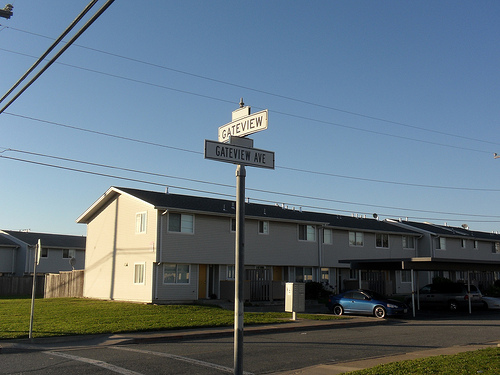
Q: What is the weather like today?
A: It is clear.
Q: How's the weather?
A: It is clear.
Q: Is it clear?
A: Yes, it is clear.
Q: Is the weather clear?
A: Yes, it is clear.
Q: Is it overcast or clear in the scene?
A: It is clear.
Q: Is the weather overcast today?
A: No, it is clear.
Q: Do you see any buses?
A: No, there are no buses.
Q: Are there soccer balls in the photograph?
A: No, there are no soccer balls.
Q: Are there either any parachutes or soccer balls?
A: No, there are no soccer balls or parachutes.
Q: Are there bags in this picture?
A: No, there are no bags.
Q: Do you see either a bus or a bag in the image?
A: No, there are no bags or buses.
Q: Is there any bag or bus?
A: No, there are no bags or buses.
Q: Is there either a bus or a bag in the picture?
A: No, there are no bags or buses.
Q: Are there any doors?
A: Yes, there is a door.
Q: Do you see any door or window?
A: Yes, there is a door.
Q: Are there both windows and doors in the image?
A: Yes, there are both a door and a window.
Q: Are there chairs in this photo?
A: No, there are no chairs.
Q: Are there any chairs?
A: No, there are no chairs.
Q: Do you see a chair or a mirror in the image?
A: No, there are no chairs or mirrors.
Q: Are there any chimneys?
A: No, there are no chimneys.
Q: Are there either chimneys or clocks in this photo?
A: No, there are no chimneys or clocks.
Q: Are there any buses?
A: No, there are no buses.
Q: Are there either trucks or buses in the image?
A: No, there are no buses or trucks.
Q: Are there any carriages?
A: No, there are no carriages.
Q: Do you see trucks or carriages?
A: No, there are no carriages or trucks.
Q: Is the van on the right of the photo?
A: Yes, the van is on the right of the image.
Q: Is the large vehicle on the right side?
A: Yes, the van is on the right of the image.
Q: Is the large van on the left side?
A: No, the van is on the right of the image.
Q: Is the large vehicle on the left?
A: No, the van is on the right of the image.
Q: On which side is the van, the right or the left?
A: The van is on the right of the image.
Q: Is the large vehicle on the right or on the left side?
A: The van is on the right of the image.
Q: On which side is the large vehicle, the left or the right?
A: The van is on the right of the image.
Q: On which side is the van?
A: The van is on the right of the image.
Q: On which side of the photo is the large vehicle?
A: The van is on the right of the image.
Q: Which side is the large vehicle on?
A: The van is on the right of the image.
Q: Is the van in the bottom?
A: Yes, the van is in the bottom of the image.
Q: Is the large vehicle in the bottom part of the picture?
A: Yes, the van is in the bottom of the image.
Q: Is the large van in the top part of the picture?
A: No, the van is in the bottom of the image.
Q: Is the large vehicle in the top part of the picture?
A: No, the van is in the bottom of the image.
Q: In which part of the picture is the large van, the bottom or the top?
A: The van is in the bottom of the image.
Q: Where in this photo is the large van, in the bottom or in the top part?
A: The van is in the bottom of the image.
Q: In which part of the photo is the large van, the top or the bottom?
A: The van is in the bottom of the image.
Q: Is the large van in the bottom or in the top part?
A: The van is in the bottom of the image.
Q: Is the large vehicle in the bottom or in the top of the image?
A: The van is in the bottom of the image.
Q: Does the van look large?
A: Yes, the van is large.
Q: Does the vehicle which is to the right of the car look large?
A: Yes, the van is large.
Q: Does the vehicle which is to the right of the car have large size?
A: Yes, the van is large.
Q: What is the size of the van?
A: The van is large.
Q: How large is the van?
A: The van is large.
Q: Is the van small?
A: No, the van is large.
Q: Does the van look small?
A: No, the van is large.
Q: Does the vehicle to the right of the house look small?
A: No, the van is large.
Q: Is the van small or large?
A: The van is large.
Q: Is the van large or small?
A: The van is large.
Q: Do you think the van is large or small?
A: The van is large.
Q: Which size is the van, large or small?
A: The van is large.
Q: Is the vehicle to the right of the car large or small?
A: The van is large.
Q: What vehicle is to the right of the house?
A: The vehicle is a van.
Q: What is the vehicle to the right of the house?
A: The vehicle is a van.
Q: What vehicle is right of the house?
A: The vehicle is a van.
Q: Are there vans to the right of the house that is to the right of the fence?
A: Yes, there is a van to the right of the house.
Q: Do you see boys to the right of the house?
A: No, there is a van to the right of the house.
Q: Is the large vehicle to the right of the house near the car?
A: Yes, the van is to the right of the house.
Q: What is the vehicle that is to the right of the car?
A: The vehicle is a van.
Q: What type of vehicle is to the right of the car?
A: The vehicle is a van.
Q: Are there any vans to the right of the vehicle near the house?
A: Yes, there is a van to the right of the car.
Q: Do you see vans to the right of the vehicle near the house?
A: Yes, there is a van to the right of the car.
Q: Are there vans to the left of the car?
A: No, the van is to the right of the car.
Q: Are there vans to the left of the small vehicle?
A: No, the van is to the right of the car.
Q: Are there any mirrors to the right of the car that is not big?
A: No, there is a van to the right of the car.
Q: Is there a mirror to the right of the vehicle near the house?
A: No, there is a van to the right of the car.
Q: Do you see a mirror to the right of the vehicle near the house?
A: No, there is a van to the right of the car.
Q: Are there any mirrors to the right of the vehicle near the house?
A: No, there is a van to the right of the car.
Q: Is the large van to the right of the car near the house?
A: Yes, the van is to the right of the car.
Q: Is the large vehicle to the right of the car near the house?
A: Yes, the van is to the right of the car.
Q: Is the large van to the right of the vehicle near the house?
A: Yes, the van is to the right of the car.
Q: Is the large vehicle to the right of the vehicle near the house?
A: Yes, the van is to the right of the car.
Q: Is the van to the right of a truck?
A: No, the van is to the right of the car.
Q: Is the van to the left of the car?
A: No, the van is to the right of the car.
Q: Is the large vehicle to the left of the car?
A: No, the van is to the right of the car.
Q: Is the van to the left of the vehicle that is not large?
A: No, the van is to the right of the car.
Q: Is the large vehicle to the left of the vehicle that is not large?
A: No, the van is to the right of the car.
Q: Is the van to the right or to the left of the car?
A: The van is to the right of the car.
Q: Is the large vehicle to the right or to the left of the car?
A: The van is to the right of the car.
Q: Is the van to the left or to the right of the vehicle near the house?
A: The van is to the right of the car.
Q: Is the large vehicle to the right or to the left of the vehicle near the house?
A: The van is to the right of the car.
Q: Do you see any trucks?
A: No, there are no trucks.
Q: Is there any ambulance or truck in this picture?
A: No, there are no trucks or ambulances.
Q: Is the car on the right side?
A: Yes, the car is on the right of the image.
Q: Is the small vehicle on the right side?
A: Yes, the car is on the right of the image.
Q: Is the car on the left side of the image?
A: No, the car is on the right of the image.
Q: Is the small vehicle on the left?
A: No, the car is on the right of the image.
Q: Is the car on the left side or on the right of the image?
A: The car is on the right of the image.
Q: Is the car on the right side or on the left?
A: The car is on the right of the image.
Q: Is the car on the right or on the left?
A: The car is on the right of the image.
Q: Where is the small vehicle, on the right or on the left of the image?
A: The car is on the right of the image.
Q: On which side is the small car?
A: The car is on the right of the image.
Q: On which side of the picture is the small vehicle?
A: The car is on the right of the image.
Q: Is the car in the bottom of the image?
A: Yes, the car is in the bottom of the image.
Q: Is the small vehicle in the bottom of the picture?
A: Yes, the car is in the bottom of the image.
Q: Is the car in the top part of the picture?
A: No, the car is in the bottom of the image.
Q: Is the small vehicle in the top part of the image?
A: No, the car is in the bottom of the image.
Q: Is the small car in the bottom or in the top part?
A: The car is in the bottom of the image.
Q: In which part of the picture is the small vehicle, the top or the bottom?
A: The car is in the bottom of the image.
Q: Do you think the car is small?
A: Yes, the car is small.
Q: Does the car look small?
A: Yes, the car is small.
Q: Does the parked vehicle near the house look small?
A: Yes, the car is small.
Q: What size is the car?
A: The car is small.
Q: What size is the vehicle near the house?
A: The car is small.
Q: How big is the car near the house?
A: The car is small.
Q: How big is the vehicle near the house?
A: The car is small.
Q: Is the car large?
A: No, the car is small.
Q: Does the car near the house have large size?
A: No, the car is small.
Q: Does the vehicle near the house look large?
A: No, the car is small.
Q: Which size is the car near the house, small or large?
A: The car is small.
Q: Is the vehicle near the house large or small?
A: The car is small.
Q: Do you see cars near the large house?
A: Yes, there is a car near the house.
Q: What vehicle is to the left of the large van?
A: The vehicle is a car.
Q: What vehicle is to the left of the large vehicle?
A: The vehicle is a car.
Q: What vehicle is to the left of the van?
A: The vehicle is a car.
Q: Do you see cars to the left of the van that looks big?
A: Yes, there is a car to the left of the van.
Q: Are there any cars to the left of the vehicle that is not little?
A: Yes, there is a car to the left of the van.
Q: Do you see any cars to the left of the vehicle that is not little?
A: Yes, there is a car to the left of the van.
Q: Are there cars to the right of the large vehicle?
A: No, the car is to the left of the van.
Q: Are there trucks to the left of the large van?
A: No, there is a car to the left of the van.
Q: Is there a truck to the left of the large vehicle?
A: No, there is a car to the left of the van.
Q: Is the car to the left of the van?
A: Yes, the car is to the left of the van.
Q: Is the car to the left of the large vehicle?
A: Yes, the car is to the left of the van.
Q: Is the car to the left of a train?
A: No, the car is to the left of the van.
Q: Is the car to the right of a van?
A: No, the car is to the left of a van.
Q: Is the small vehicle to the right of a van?
A: No, the car is to the left of a van.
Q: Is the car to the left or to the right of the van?
A: The car is to the left of the van.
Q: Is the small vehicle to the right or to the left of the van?
A: The car is to the left of the van.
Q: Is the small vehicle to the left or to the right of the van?
A: The car is to the left of the van.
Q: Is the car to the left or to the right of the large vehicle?
A: The car is to the left of the van.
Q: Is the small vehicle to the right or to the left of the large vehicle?
A: The car is to the left of the van.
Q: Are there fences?
A: Yes, there is a fence.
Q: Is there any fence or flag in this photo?
A: Yes, there is a fence.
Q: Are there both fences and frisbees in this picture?
A: No, there is a fence but no frisbees.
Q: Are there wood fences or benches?
A: Yes, there is a wood fence.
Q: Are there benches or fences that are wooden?
A: Yes, the fence is wooden.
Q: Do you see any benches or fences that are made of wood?
A: Yes, the fence is made of wood.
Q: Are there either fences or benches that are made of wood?
A: Yes, the fence is made of wood.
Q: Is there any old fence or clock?
A: Yes, there is an old fence.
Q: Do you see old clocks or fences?
A: Yes, there is an old fence.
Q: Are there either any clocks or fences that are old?
A: Yes, the fence is old.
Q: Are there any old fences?
A: Yes, there is an old fence.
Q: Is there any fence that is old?
A: Yes, there is a fence that is old.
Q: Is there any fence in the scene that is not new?
A: Yes, there is a old fence.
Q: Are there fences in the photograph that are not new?
A: Yes, there is a old fence.